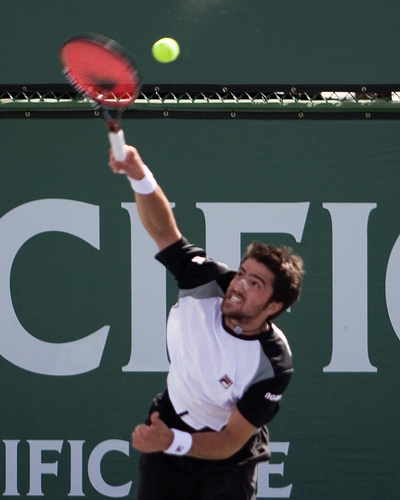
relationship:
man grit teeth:
[108, 142, 306, 497] [226, 294, 242, 302]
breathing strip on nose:
[239, 276, 249, 290] [230, 273, 250, 290]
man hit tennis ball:
[108, 142, 306, 497] [144, 33, 181, 67]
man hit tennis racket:
[108, 142, 306, 497] [50, 30, 148, 169]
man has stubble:
[108, 142, 306, 497] [219, 250, 274, 324]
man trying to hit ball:
[108, 142, 306, 497] [152, 36, 180, 63]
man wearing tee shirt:
[108, 142, 304, 494] [154, 231, 295, 436]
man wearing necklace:
[108, 142, 304, 494] [227, 318, 264, 334]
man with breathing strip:
[108, 142, 306, 497] [239, 276, 249, 290]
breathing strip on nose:
[239, 276, 249, 290] [232, 276, 249, 292]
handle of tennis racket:
[96, 105, 127, 174] [59, 33, 140, 173]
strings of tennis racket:
[67, 41, 138, 107] [59, 33, 140, 173]